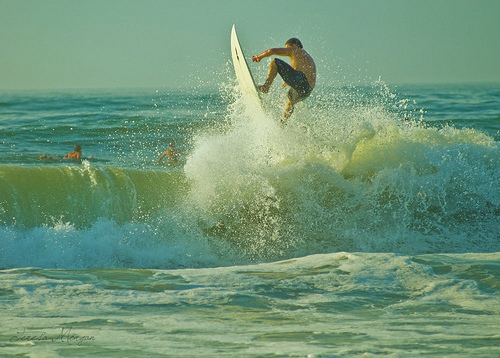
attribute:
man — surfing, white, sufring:
[229, 22, 335, 105]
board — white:
[219, 17, 260, 97]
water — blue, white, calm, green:
[151, 111, 297, 258]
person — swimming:
[56, 131, 98, 171]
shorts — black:
[275, 54, 298, 101]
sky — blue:
[56, 11, 159, 64]